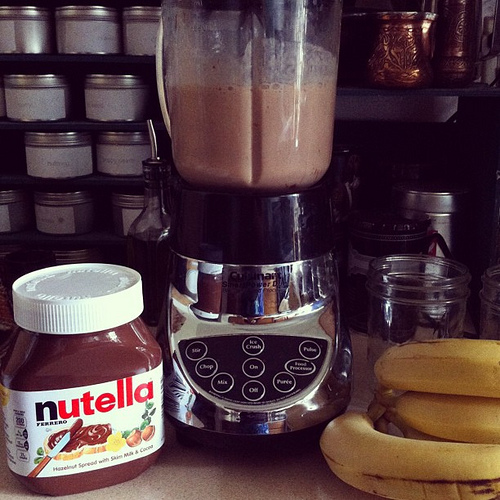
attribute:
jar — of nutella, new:
[2, 257, 172, 499]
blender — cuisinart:
[149, 1, 359, 461]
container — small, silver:
[51, 1, 126, 59]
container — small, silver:
[81, 66, 150, 125]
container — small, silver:
[1, 69, 75, 124]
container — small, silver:
[21, 126, 99, 182]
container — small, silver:
[90, 127, 155, 181]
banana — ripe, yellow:
[369, 335, 500, 404]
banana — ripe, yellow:
[367, 379, 499, 452]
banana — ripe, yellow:
[315, 404, 499, 499]